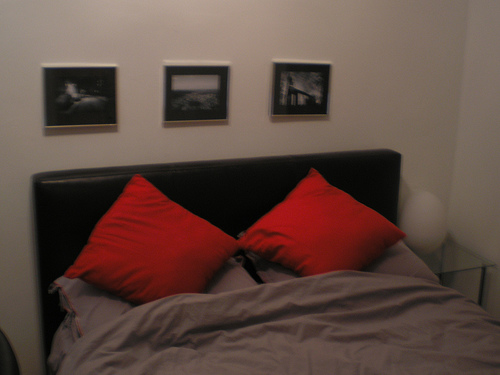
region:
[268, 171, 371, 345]
Red pillow on bed.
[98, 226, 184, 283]
Red pillow on bed.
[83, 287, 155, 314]
Tan pillow on bed.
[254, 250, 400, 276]
Tan pillow on bed.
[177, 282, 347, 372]
Sheets are tan on bed.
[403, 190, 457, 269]
White object on nightstand near bed.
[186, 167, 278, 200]
Dark headboard on bed near wall.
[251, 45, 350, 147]
Picture hanging above bed.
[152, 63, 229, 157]
Picture hanging above bed.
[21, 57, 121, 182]
Picture hanging above bed.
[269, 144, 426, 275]
square red pillow on bed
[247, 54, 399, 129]
gray and white photo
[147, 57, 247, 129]
black and white photo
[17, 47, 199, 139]
black and white photo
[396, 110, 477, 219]
wall next to bed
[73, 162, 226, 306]
square red pillow on bed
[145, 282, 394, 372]
gray beige comforter on bed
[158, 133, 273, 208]
all black bed post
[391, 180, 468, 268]
random light on stand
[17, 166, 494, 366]
queen size bed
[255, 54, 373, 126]
black and white photo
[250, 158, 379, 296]
red square pillow on bed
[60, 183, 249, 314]
red square pillow on bed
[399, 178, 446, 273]
egg shaped light on stand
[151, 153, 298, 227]
black post on bed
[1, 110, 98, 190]
wall behind black post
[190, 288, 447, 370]
gray comforter on bed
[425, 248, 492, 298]
glass nightstand by bed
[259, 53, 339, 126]
picture on a wall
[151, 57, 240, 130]
picture on a wall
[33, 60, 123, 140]
picture on a wall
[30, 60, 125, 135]
picture in a frame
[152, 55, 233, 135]
picture in a frame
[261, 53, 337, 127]
picture in a frame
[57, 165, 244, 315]
large red pillow on a bed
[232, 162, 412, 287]
large red pillow on a bed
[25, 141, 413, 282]
black headboard of a bed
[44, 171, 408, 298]
two large red pillows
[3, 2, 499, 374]
a bed in bedroom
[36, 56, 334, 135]
Framed photographs on wall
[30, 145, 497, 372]
a bed with red pillows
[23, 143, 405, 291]
a brown vinyl headboard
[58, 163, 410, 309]
a pair of red throw pillows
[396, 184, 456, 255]
a white egg-shaped object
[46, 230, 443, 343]
a pair of bed pillows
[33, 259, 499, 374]
a white comforter on bed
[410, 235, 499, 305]
glass table stand in corner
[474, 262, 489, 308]
a table stand leg